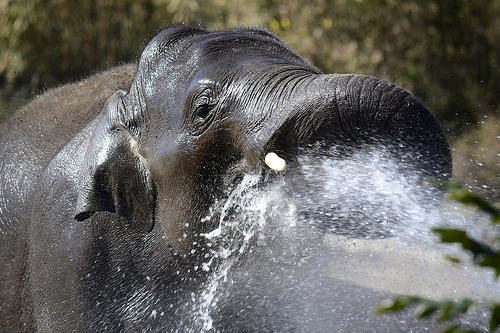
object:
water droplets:
[326, 135, 466, 245]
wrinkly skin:
[157, 27, 416, 167]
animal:
[1, 26, 453, 331]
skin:
[99, 79, 169, 136]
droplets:
[262, 241, 342, 318]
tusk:
[266, 150, 287, 174]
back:
[0, 58, 186, 210]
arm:
[29, 250, 151, 332]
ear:
[60, 95, 175, 239]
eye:
[192, 103, 213, 118]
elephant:
[0, 25, 472, 333]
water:
[59, 78, 499, 331]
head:
[57, 20, 453, 219]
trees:
[0, 1, 495, 140]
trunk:
[298, 66, 456, 259]